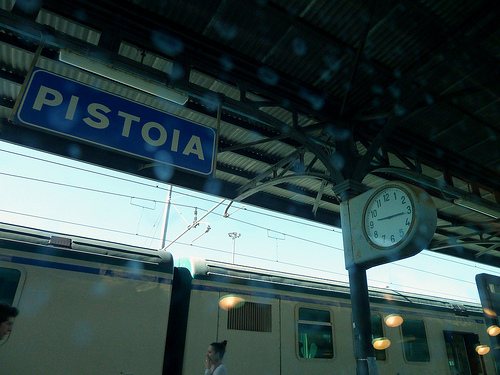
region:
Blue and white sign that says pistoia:
[11, 61, 222, 198]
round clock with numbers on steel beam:
[335, 169, 436, 271]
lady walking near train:
[198, 324, 232, 372]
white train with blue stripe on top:
[13, 211, 493, 372]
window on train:
[283, 304, 345, 368]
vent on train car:
[227, 300, 279, 337]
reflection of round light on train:
[380, 311, 416, 333]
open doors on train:
[438, 328, 488, 374]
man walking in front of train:
[0, 304, 25, 346]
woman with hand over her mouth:
[183, 326, 236, 373]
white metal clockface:
[362, 187, 417, 242]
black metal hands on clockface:
[377, 205, 409, 227]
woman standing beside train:
[189, 335, 238, 373]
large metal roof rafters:
[265, 75, 342, 158]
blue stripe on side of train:
[65, 261, 163, 291]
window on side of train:
[292, 304, 342, 363]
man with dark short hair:
[0, 301, 25, 346]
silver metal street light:
[223, 227, 252, 263]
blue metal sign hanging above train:
[12, 62, 230, 201]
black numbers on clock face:
[377, 190, 407, 209]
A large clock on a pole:
[353, 174, 426, 298]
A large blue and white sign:
[5, 54, 231, 189]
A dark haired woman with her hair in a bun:
[201, 328, 236, 373]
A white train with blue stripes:
[21, 207, 296, 374]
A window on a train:
[284, 306, 344, 367]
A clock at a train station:
[206, 160, 443, 373]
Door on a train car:
[424, 304, 495, 370]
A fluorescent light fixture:
[65, 29, 199, 106]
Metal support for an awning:
[250, 154, 335, 206]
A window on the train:
[396, 307, 441, 362]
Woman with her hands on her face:
[204, 339, 229, 374]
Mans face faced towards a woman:
[0, 302, 17, 343]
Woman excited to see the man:
[0, 301, 227, 373]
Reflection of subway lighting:
[370, 310, 405, 352]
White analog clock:
[360, 183, 415, 252]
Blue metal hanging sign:
[17, 67, 214, 178]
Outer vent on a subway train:
[225, 298, 275, 333]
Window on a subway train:
[295, 300, 335, 361]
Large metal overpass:
[0, 0, 497, 263]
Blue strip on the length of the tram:
[0, 245, 486, 327]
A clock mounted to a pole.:
[329, 159, 427, 274]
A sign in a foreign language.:
[13, 59, 221, 174]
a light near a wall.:
[216, 280, 249, 307]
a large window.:
[0, 139, 358, 301]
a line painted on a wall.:
[143, 267, 193, 372]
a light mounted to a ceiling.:
[43, 30, 209, 111]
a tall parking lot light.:
[223, 225, 244, 273]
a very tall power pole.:
[156, 176, 181, 261]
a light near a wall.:
[375, 288, 412, 341]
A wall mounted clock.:
[340, 173, 444, 274]